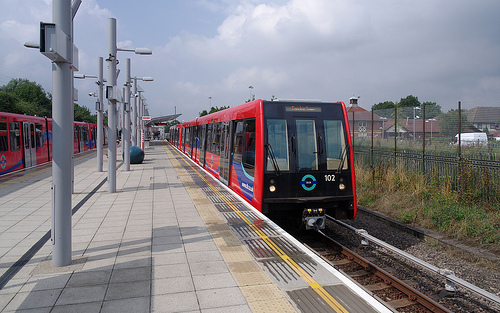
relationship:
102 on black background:
[324, 174, 335, 181] [270, 174, 350, 195]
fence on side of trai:
[351, 102, 498, 206] [168, 98, 357, 229]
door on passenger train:
[20, 117, 37, 169] [3, 106, 111, 182]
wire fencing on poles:
[427, 104, 457, 155] [392, 100, 428, 173]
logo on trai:
[298, 171, 320, 193] [168, 98, 357, 229]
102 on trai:
[324, 174, 335, 181] [168, 98, 357, 229]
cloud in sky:
[0, 1, 493, 96] [2, 2, 499, 121]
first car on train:
[228, 95, 361, 226] [119, 66, 395, 235]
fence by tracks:
[351, 102, 498, 206] [284, 210, 499, 311]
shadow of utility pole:
[1, 217, 250, 268] [23, 0, 83, 267]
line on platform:
[288, 257, 324, 299] [0, 139, 369, 311]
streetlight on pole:
[111, 44, 160, 64] [18, 74, 128, 271]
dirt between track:
[362, 250, 383, 260] [322, 210, 498, 310]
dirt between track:
[362, 250, 383, 260] [313, 226, 446, 311]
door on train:
[23, 121, 37, 168] [1, 105, 106, 184]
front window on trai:
[325, 120, 348, 171] [168, 98, 357, 229]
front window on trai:
[297, 117, 317, 173] [168, 98, 357, 229]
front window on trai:
[266, 119, 288, 173] [168, 98, 357, 229]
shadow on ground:
[1, 216, 270, 277] [9, 161, 305, 311]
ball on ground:
[122, 146, 146, 164] [78, 135, 189, 203]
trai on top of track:
[168, 98, 357, 229] [300, 225, 450, 309]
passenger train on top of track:
[0, 110, 108, 178] [300, 225, 450, 309]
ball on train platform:
[116, 144, 170, 172] [29, 142, 283, 311]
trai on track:
[168, 98, 357, 229] [300, 225, 450, 309]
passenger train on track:
[0, 110, 108, 178] [300, 225, 450, 309]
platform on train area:
[12, 145, 246, 312] [6, 5, 363, 308]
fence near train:
[351, 102, 498, 206] [131, 79, 406, 217]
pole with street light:
[106, 16, 116, 193] [117, 47, 152, 54]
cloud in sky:
[175, 2, 363, 82] [2, 2, 499, 121]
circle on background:
[299, 174, 318, 189] [265, 171, 350, 201]